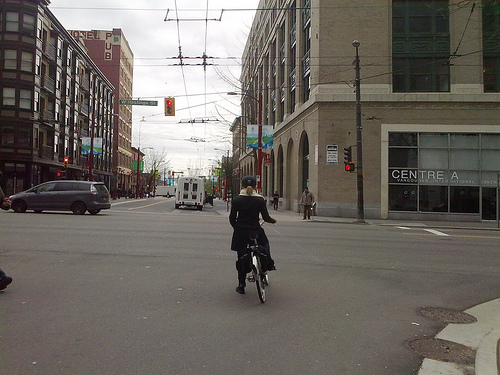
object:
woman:
[230, 175, 278, 294]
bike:
[244, 214, 270, 303]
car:
[8, 179, 112, 215]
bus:
[173, 177, 204, 209]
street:
[105, 195, 239, 215]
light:
[166, 99, 173, 105]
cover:
[420, 304, 474, 325]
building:
[0, 0, 117, 204]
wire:
[0, 62, 454, 68]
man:
[298, 186, 315, 220]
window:
[21, 51, 34, 61]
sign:
[246, 124, 260, 149]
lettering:
[450, 170, 460, 181]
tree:
[141, 150, 171, 199]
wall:
[314, 101, 500, 220]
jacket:
[228, 187, 275, 252]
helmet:
[239, 175, 260, 185]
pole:
[351, 39, 363, 224]